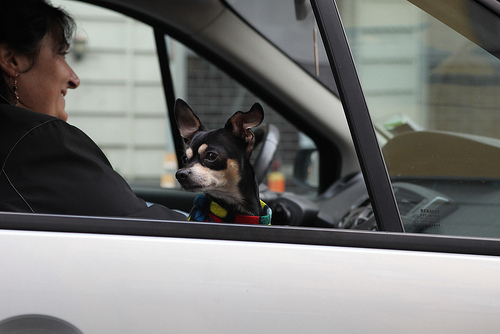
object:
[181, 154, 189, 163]
eye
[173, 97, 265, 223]
dog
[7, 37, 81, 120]
face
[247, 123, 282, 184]
steering wheel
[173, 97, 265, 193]
head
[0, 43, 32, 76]
ear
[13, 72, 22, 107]
earing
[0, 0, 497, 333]
door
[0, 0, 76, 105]
hair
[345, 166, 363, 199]
ground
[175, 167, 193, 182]
nose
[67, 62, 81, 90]
nose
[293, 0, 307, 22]
mirror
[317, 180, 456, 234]
dash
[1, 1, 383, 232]
window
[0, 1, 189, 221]
person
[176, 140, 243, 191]
face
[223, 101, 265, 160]
ear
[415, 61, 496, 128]
board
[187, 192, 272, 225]
clothes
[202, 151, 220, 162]
eye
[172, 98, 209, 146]
ear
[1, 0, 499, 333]
car